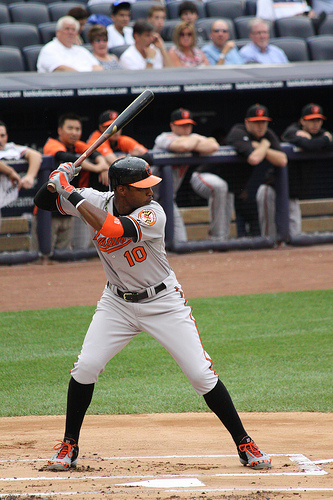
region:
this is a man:
[71, 156, 225, 367]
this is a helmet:
[107, 159, 156, 183]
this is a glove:
[54, 172, 73, 192]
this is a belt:
[115, 288, 144, 298]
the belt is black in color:
[134, 294, 143, 298]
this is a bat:
[110, 98, 161, 129]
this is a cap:
[173, 107, 195, 123]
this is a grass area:
[253, 309, 308, 379]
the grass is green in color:
[257, 324, 290, 373]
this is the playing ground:
[100, 431, 185, 497]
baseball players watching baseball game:
[32, 107, 307, 284]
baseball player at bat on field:
[33, 120, 291, 493]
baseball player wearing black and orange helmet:
[40, 144, 214, 296]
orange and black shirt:
[35, 118, 99, 215]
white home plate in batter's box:
[41, 394, 220, 495]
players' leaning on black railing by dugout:
[141, 108, 330, 266]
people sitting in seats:
[24, 1, 318, 100]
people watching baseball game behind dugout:
[33, 5, 329, 345]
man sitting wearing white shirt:
[25, 1, 104, 95]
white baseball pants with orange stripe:
[61, 144, 227, 411]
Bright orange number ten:
[121, 246, 151, 267]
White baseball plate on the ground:
[108, 464, 208, 496]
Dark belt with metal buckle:
[103, 281, 177, 306]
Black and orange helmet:
[101, 150, 166, 194]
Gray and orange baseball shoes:
[38, 425, 276, 473]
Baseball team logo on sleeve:
[133, 204, 162, 228]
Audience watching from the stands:
[42, 10, 283, 75]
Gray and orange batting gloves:
[42, 159, 89, 201]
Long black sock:
[202, 381, 253, 442]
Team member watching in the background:
[223, 101, 310, 252]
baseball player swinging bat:
[32, 89, 275, 470]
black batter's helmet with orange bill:
[109, 155, 162, 190]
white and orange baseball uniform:
[50, 186, 218, 396]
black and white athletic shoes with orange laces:
[48, 436, 78, 471]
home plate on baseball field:
[112, 474, 205, 490]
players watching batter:
[152, 102, 331, 238]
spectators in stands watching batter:
[35, 0, 292, 70]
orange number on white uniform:
[123, 245, 147, 266]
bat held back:
[46, 86, 154, 195]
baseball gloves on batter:
[47, 160, 82, 199]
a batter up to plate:
[24, 87, 199, 473]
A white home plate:
[106, 474, 208, 491]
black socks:
[220, 376, 247, 446]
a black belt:
[105, 281, 179, 303]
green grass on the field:
[243, 295, 311, 395]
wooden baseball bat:
[70, 86, 166, 157]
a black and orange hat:
[108, 156, 163, 189]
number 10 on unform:
[122, 247, 148, 273]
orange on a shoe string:
[247, 439, 262, 459]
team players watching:
[10, 99, 323, 158]